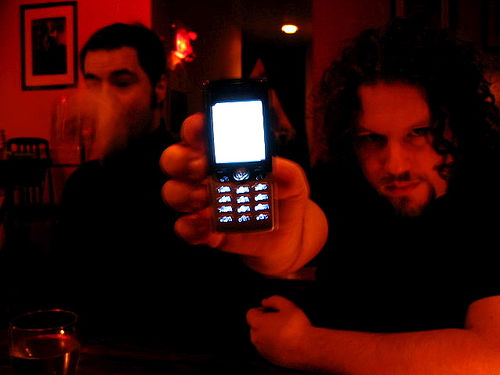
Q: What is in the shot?
A: The phone.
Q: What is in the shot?
A: The man.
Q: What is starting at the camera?
A: The male's face with long hair.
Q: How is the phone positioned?
A: Front facing.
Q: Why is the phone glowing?
A: It is on.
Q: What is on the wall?
A: Picture.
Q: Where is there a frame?
A: Around picture.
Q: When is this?
A: Nighttime.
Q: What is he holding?
A: Phone.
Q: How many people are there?
A: Two.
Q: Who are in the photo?
A: People.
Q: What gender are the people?
A: Male.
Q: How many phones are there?
A: One.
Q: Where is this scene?
A: Bar.